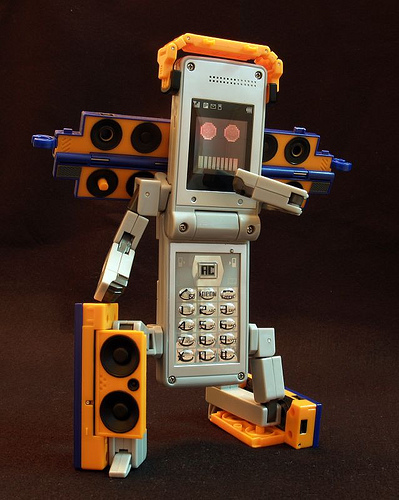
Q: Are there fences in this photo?
A: No, there are no fences.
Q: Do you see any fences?
A: No, there are no fences.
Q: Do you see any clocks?
A: No, there are no clocks.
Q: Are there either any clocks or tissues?
A: No, there are no clocks or tissues.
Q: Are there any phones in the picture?
A: Yes, there is a phone.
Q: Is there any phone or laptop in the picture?
A: Yes, there is a phone.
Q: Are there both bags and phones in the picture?
A: No, there is a phone but no bags.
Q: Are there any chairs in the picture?
A: No, there are no chairs.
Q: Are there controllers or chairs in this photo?
A: No, there are no chairs or controllers.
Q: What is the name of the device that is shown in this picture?
A: The device is a phone.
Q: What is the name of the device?
A: The device is a phone.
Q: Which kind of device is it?
A: The device is a phone.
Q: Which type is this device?
A: That is a phone.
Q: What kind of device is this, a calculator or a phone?
A: That is a phone.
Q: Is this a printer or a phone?
A: This is a phone.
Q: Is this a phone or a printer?
A: This is a phone.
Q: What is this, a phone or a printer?
A: This is a phone.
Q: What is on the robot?
A: The phone is on the robot.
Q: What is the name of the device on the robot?
A: The device is a phone.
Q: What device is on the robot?
A: The device is a phone.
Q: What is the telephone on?
A: The telephone is on the robot.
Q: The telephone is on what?
A: The telephone is on the robot.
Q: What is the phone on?
A: The telephone is on the robot.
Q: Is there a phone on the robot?
A: Yes, there is a phone on the robot.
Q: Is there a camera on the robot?
A: No, there is a phone on the robot.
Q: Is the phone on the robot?
A: Yes, the phone is on the robot.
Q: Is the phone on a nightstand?
A: No, the phone is on the robot.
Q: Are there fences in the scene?
A: No, there are no fences.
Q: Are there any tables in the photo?
A: Yes, there is a table.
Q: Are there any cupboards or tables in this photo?
A: Yes, there is a table.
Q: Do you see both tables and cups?
A: No, there is a table but no cups.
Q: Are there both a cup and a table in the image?
A: No, there is a table but no cups.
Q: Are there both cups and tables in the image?
A: No, there is a table but no cups.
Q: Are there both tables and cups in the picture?
A: No, there is a table but no cups.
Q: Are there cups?
A: No, there are no cups.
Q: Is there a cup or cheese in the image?
A: No, there are no cups or cheese.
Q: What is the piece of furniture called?
A: The piece of furniture is a table.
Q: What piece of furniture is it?
A: The piece of furniture is a table.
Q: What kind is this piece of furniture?
A: This is a table.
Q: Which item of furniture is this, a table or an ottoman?
A: This is a table.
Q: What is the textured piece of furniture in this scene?
A: The piece of furniture is a table.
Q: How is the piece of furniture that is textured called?
A: The piece of furniture is a table.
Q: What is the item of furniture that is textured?
A: The piece of furniture is a table.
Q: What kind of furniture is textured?
A: The furniture is a table.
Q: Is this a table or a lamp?
A: This is a table.